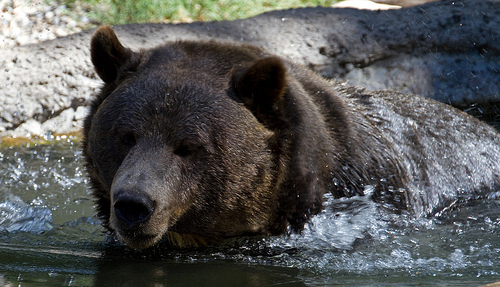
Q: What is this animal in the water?
A: A brown bear.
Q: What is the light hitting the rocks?
A: Sunlight.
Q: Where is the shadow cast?
A: On the rocks.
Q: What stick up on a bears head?
A: Ears.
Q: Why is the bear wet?
A: Swimming.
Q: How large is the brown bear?
A: Very large and big.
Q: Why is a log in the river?
A: It fell.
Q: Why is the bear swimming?
A: To catch fish.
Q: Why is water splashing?
A: Bear crossing the river.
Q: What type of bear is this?
A: Brown bear.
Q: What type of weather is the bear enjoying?
A: A sunny day.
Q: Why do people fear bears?
A: You can be eaten.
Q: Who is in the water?
A: A bear.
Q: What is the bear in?
A: The water.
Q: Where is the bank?
A: Behind the bear next to the water.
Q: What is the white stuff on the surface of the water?
A: Ripples and splashes.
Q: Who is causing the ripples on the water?
A: The bear.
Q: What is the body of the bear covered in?
A: Brown fur.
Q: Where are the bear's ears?
A: On top of the bear's head.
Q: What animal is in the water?
A: A bear.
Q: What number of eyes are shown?
A: Two.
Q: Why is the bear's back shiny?
A: Because it is wet.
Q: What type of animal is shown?
A: Bear.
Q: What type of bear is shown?
A: Brown bear.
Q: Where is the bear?
A: Water.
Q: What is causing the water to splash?
A: Bear.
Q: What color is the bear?
A: Dark brown.